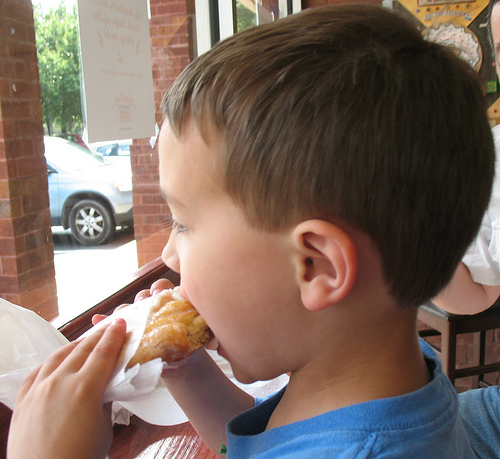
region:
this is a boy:
[84, 2, 479, 447]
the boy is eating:
[48, 221, 252, 419]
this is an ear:
[288, 218, 353, 323]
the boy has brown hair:
[175, 6, 493, 317]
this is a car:
[40, 111, 131, 259]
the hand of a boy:
[1, 325, 129, 455]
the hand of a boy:
[97, 279, 252, 446]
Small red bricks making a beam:
[10, 241, 55, 268]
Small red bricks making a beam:
[3, 209, 53, 248]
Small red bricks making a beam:
[1, 173, 48, 215]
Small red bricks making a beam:
[0, 131, 45, 173]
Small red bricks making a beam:
[0, 93, 43, 135]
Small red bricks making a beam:
[5, 59, 38, 102]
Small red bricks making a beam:
[128, 209, 157, 241]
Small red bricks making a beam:
[126, 175, 153, 219]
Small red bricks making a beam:
[155, 16, 195, 52]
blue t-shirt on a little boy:
[225, 337, 468, 457]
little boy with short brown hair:
[161, 58, 496, 388]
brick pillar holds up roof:
[2, 5, 59, 313]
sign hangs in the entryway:
[75, 3, 155, 142]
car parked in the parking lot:
[45, 135, 132, 245]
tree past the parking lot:
[32, 1, 82, 141]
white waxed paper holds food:
[1, 297, 161, 407]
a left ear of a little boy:
[286, 221, 353, 306]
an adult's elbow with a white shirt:
[430, 254, 498, 318]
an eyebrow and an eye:
[161, 180, 195, 240]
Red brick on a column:
[150, 4, 179, 23]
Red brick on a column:
[149, 14, 189, 53]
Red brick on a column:
[147, 52, 179, 87]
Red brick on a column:
[128, 139, 152, 162]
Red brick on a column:
[128, 159, 158, 184]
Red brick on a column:
[129, 181, 154, 201]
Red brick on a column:
[135, 207, 160, 232]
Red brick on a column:
[10, 15, 36, 55]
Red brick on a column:
[18, 80, 43, 135]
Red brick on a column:
[4, 170, 39, 237]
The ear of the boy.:
[293, 222, 355, 311]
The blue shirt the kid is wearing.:
[225, 337, 452, 457]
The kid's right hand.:
[10, 325, 121, 453]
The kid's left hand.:
[91, 279, 188, 366]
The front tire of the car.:
[70, 199, 110, 245]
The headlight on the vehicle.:
[108, 177, 130, 191]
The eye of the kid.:
[167, 214, 187, 231]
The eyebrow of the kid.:
[157, 184, 187, 206]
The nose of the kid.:
[162, 243, 180, 268]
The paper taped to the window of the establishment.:
[73, 2, 160, 142]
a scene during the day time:
[6, 85, 496, 442]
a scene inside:
[15, 90, 498, 457]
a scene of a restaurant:
[11, 18, 496, 453]